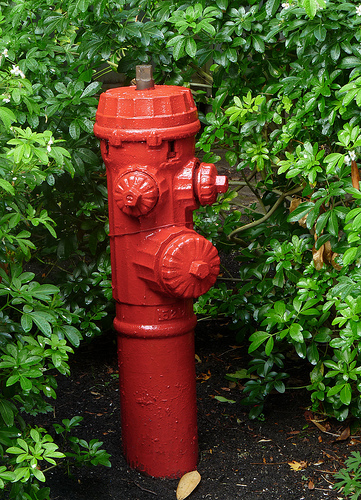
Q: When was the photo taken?
A: During the day.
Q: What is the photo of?
A: A fire hydrant.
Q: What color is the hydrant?
A: Red.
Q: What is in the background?
A: Bushes.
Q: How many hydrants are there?
A: One.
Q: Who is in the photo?
A: No one.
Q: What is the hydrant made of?
A: Metal.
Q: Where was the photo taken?
A: Near hydrant.